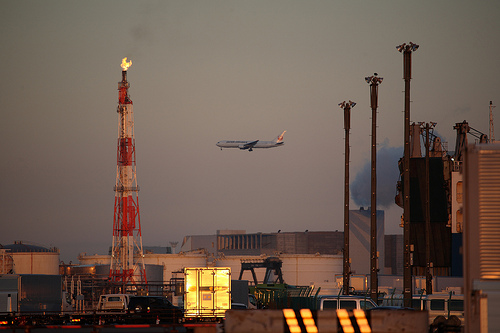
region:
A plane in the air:
[213, 132, 297, 154]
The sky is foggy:
[6, 12, 493, 226]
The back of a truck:
[181, 260, 240, 322]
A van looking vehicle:
[127, 292, 179, 324]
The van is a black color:
[128, 294, 183, 324]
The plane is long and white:
[210, 130, 290, 150]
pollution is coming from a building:
[340, 116, 432, 216]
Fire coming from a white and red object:
[116, 56, 133, 78]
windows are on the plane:
[225, 135, 250, 145]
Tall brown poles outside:
[335, 37, 435, 303]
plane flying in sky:
[203, 118, 290, 169]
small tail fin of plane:
[272, 127, 290, 147]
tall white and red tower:
[94, 58, 145, 286]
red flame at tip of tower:
[118, 50, 132, 81]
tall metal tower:
[103, 66, 143, 301]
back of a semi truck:
[179, 266, 239, 323]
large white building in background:
[182, 223, 341, 273]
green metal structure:
[237, 257, 288, 293]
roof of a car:
[316, 291, 383, 306]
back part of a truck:
[90, 293, 126, 312]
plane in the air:
[191, 92, 311, 189]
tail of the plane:
[262, 111, 299, 161]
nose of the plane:
[205, 135, 225, 155]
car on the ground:
[136, 280, 181, 325]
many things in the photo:
[31, 111, 481, 326]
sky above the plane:
[151, 65, 223, 120]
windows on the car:
[316, 290, 376, 310]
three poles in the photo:
[305, 15, 430, 280]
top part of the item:
[100, 40, 156, 90]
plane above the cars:
[213, 117, 298, 177]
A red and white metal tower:
[110, 60, 147, 288]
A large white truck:
[172, 267, 229, 317]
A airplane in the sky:
[212, 127, 291, 152]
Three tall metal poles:
[337, 41, 417, 305]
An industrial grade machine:
[240, 260, 316, 306]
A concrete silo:
[0, 242, 63, 272]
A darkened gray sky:
[2, 0, 499, 247]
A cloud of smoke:
[350, 145, 398, 207]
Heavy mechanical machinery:
[404, 121, 489, 154]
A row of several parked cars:
[380, 292, 467, 327]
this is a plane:
[203, 113, 311, 165]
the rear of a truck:
[166, 253, 243, 315]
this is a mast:
[94, 43, 158, 302]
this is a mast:
[316, 79, 358, 294]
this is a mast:
[354, 51, 386, 311]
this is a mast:
[377, 29, 429, 314]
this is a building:
[81, 218, 212, 331]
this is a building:
[179, 211, 218, 271]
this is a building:
[261, 217, 346, 277]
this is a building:
[432, 135, 492, 286]